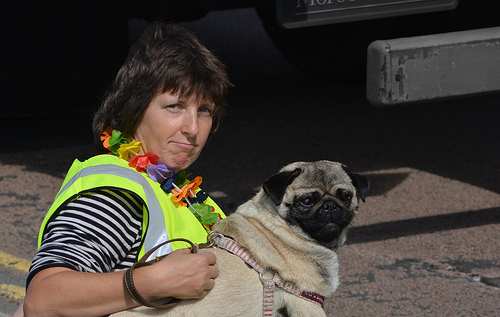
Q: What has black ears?
A: The brown pug.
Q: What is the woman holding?
A: A small dog.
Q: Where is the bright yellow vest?
A: On the woman.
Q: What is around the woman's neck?
A: A lei.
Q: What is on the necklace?
A: Different color flowers.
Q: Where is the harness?
A: On the dog.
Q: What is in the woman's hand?
A: A leash.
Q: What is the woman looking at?
A: The camera.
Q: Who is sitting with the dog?
A: A woman.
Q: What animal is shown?
A: Dog.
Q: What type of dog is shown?
A: Pug.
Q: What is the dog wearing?
A: Harness.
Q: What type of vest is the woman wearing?
A: Safety vest.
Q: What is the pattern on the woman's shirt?
A: Stripes.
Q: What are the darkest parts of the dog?
A: Face and ears.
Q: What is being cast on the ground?
A: Shadow.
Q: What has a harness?
A: The dog.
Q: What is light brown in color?
A: The dog.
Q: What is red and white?
A: The dog's harness.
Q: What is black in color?
A: The woman's hair.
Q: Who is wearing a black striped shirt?
A: The woman.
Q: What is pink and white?
A: Harness on the dog.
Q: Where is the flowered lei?
A: Around the woman's neck.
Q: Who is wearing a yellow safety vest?
A: The woman.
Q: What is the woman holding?
A: A pug.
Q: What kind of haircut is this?
A: Mullet.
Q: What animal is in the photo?
A: A dog.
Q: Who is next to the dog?
A: A woman.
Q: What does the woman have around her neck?
A: A lei.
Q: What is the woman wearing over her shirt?
A: A vest.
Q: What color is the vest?
A: Yellow and silver.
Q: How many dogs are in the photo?
A: One.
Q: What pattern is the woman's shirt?
A: Striped.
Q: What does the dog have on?
A: A harness.